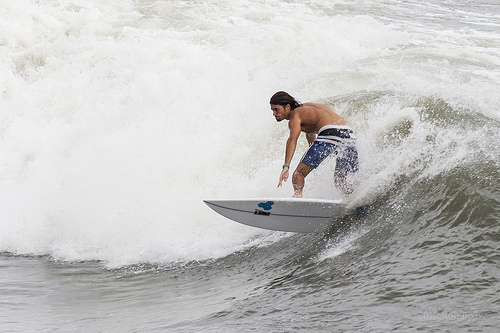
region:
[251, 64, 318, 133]
head of a surfer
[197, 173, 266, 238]
front of the board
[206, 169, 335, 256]
white board in the photo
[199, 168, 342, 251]
board under the man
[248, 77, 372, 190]
man on a board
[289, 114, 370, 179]
shorts on the man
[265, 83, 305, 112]
hair on man's head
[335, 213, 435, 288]
water next to man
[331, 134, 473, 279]
wave forming in water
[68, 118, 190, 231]
white water in photo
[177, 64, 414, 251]
man in the water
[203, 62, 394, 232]
man surfing in water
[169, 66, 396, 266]
surfer riding a wave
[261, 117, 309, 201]
arm of the surfer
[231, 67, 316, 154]
head of the surfer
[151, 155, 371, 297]
white board under surfer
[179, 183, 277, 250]
tip of the board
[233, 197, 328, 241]
bottom of the board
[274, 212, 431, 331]
water next to surfer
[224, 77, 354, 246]
surfer on white board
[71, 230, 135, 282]
white and gray ocean waves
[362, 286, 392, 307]
white and gray ocean waves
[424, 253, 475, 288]
white and gray ocean waves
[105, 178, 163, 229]
white and gray ocean waves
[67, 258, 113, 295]
white and gray ocean waves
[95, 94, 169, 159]
white and gray ocean waves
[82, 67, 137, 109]
white and gray ocean waves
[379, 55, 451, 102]
white and gray ocean waves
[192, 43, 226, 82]
white and gray ocean waves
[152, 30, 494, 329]
guy at the beach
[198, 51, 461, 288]
guy on a surfboard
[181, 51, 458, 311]
guy on a white surfboard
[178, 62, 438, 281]
guy hair wet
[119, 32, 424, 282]
guy wearing blue and white swim shorts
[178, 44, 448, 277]
guy leaning on surfboard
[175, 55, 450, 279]
guy turned to the side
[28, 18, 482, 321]
guy riding a wave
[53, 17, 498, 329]
guy arm extended to the ground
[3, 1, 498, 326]
guy enjoying the waves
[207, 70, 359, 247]
surfer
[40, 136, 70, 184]
white and gray ocean waves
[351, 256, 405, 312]
white and gray ocean waves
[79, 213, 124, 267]
white and gray ocean waves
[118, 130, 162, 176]
white and gray ocean waves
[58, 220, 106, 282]
white and gray ocean waves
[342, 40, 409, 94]
white and gray ocean waves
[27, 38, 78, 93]
white and gray ocean waves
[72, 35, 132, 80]
white and gray ocean waves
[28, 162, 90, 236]
white and gray ocean waves